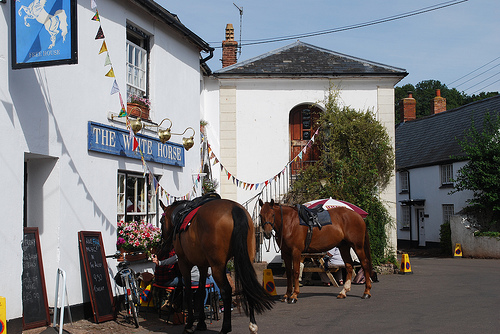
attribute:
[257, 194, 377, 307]
horse — looking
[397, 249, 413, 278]
cone — yellow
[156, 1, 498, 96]
sky — blue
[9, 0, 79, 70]
sign — blue, white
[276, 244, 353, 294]
table — wooden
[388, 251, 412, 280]
cone — yellow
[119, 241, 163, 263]
box — white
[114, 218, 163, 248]
flowers — pink 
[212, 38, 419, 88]
shingles — black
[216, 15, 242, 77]
chimney — brick, tall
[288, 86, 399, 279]
plant — green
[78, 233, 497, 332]
asphalt — black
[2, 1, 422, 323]
building — white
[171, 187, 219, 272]
coat — brown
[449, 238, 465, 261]
cone — yellow